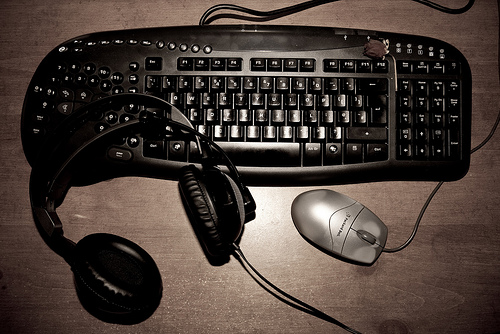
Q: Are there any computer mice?
A: Yes, there is a computer mouse.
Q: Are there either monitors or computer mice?
A: Yes, there is a computer mouse.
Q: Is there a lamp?
A: No, there are no lamps.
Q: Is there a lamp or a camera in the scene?
A: No, there are no lamps or cameras.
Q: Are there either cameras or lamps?
A: No, there are no lamps or cameras.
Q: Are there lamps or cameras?
A: No, there are no lamps or cameras.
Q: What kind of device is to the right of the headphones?
A: The device is a computer mouse.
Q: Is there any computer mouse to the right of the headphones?
A: Yes, there is a computer mouse to the right of the headphones.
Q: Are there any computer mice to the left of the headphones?
A: No, the computer mouse is to the right of the headphones.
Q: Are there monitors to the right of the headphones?
A: No, there is a computer mouse to the right of the headphones.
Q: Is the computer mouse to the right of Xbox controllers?
A: No, the computer mouse is to the right of the headphones.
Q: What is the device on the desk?
A: The device is a computer mouse.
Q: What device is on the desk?
A: The device is a computer mouse.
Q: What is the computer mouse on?
A: The computer mouse is on the desk.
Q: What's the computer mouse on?
A: The computer mouse is on the desk.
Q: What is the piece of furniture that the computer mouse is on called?
A: The piece of furniture is a desk.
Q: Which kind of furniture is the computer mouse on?
A: The computer mouse is on the desk.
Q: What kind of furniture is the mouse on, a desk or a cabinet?
A: The mouse is on a desk.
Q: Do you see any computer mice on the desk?
A: Yes, there is a computer mouse on the desk.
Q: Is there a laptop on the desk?
A: No, there is a computer mouse on the desk.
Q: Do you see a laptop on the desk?
A: No, there is a computer mouse on the desk.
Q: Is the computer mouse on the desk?
A: Yes, the computer mouse is on the desk.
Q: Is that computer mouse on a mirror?
A: No, the computer mouse is on the desk.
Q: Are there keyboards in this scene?
A: Yes, there is a keyboard.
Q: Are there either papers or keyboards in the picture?
A: Yes, there is a keyboard.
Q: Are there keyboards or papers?
A: Yes, there is a keyboard.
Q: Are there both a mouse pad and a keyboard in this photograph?
A: No, there is a keyboard but no mouse pads.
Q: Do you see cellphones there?
A: No, there are no cellphones.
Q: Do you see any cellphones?
A: No, there are no cellphones.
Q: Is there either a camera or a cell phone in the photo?
A: No, there are no cell phones or cameras.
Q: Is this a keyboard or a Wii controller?
A: This is a keyboard.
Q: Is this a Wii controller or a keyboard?
A: This is a keyboard.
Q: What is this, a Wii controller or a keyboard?
A: This is a keyboard.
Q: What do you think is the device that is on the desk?
A: The device is a keyboard.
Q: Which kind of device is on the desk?
A: The device is a keyboard.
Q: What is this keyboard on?
A: The keyboard is on the desk.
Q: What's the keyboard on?
A: The keyboard is on the desk.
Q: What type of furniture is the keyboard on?
A: The keyboard is on the desk.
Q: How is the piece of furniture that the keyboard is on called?
A: The piece of furniture is a desk.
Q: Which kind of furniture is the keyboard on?
A: The keyboard is on the desk.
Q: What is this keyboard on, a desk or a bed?
A: The keyboard is on a desk.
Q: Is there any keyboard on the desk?
A: Yes, there is a keyboard on the desk.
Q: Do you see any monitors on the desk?
A: No, there is a keyboard on the desk.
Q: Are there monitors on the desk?
A: No, there is a keyboard on the desk.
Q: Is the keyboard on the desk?
A: Yes, the keyboard is on the desk.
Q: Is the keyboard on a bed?
A: No, the keyboard is on the desk.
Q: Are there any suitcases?
A: No, there are no suitcases.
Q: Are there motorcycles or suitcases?
A: No, there are no suitcases or motorcycles.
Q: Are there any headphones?
A: Yes, there are headphones.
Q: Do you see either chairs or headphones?
A: Yes, there are headphones.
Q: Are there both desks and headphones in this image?
A: Yes, there are both headphones and a desk.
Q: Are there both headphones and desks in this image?
A: Yes, there are both headphones and a desk.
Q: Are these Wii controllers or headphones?
A: These are headphones.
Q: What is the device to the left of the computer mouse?
A: The device is headphones.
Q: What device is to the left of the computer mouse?
A: The device is headphones.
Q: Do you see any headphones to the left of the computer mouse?
A: Yes, there are headphones to the left of the computer mouse.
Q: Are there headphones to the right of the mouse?
A: No, the headphones are to the left of the mouse.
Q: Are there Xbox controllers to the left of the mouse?
A: No, there are headphones to the left of the mouse.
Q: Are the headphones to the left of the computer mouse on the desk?
A: Yes, the headphones are to the left of the computer mouse.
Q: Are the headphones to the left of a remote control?
A: No, the headphones are to the left of the computer mouse.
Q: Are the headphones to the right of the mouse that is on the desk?
A: No, the headphones are to the left of the mouse.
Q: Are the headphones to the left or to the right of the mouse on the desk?
A: The headphones are to the left of the mouse.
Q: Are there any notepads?
A: No, there are no notepads.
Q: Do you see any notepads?
A: No, there are no notepads.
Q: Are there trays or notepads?
A: No, there are no notepads or trays.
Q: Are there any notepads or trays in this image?
A: No, there are no notepads or trays.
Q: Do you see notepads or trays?
A: No, there are no notepads or trays.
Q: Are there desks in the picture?
A: Yes, there is a desk.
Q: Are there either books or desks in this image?
A: Yes, there is a desk.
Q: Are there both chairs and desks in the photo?
A: No, there is a desk but no chairs.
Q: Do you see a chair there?
A: No, there are no chairs.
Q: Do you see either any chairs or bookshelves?
A: No, there are no chairs or bookshelves.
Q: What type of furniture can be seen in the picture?
A: The furniture is a desk.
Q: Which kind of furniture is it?
A: The piece of furniture is a desk.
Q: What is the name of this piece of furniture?
A: This is a desk.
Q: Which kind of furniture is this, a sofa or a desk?
A: This is a desk.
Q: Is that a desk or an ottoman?
A: That is a desk.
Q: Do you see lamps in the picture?
A: No, there are no lamps.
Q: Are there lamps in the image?
A: No, there are no lamps.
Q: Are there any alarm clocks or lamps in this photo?
A: No, there are no lamps or alarm clocks.